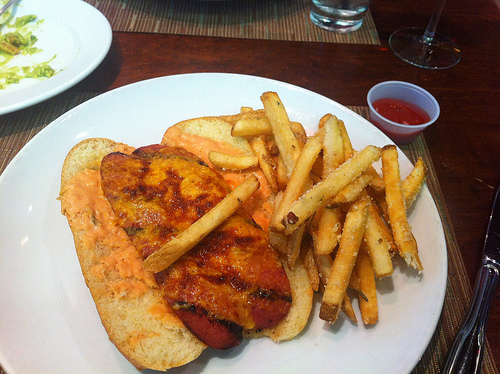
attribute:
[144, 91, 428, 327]
fries — brown, salted, piled, pieced, potato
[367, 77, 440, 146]
cup — plastic, small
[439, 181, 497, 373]
knife — stainless steel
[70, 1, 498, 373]
table — wooden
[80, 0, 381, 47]
placemat — grey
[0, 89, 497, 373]
placemat — grey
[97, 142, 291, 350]
meat — brown, split open, grilled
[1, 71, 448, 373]
plate — white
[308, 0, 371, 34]
glass — clear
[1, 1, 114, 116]
plate — almost empty, white